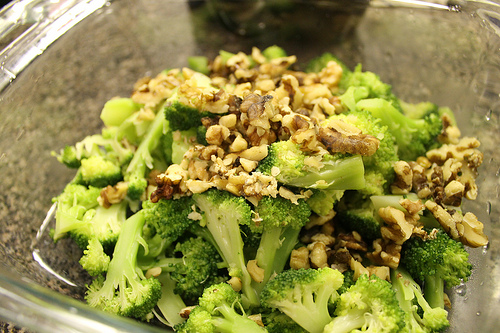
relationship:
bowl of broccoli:
[45, 22, 112, 122] [204, 91, 443, 298]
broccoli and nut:
[204, 91, 443, 298] [266, 94, 287, 127]